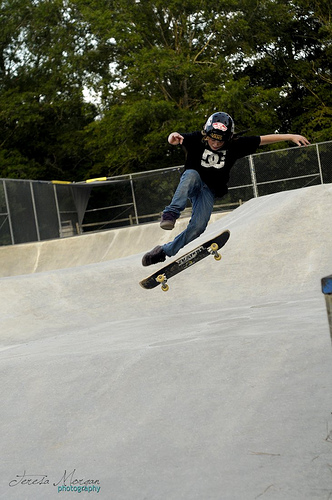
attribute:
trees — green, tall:
[2, 1, 330, 182]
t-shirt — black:
[179, 132, 261, 199]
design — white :
[199, 149, 227, 169]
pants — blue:
[120, 159, 229, 274]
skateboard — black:
[140, 229, 232, 291]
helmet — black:
[198, 110, 234, 146]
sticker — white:
[211, 120, 228, 131]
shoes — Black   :
[122, 245, 203, 268]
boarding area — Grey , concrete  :
[1, 183, 331, 499]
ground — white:
[0, 179, 331, 498]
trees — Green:
[0, 2, 330, 210]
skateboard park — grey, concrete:
[0, 181, 330, 497]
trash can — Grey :
[53, 216, 85, 238]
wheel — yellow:
[210, 240, 219, 252]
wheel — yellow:
[212, 253, 221, 260]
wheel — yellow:
[154, 272, 165, 281]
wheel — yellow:
[162, 284, 169, 291]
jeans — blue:
[141, 167, 214, 259]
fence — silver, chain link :
[0, 139, 331, 247]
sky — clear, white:
[1, 3, 330, 135]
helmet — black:
[196, 109, 242, 145]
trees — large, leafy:
[1, 2, 330, 158]